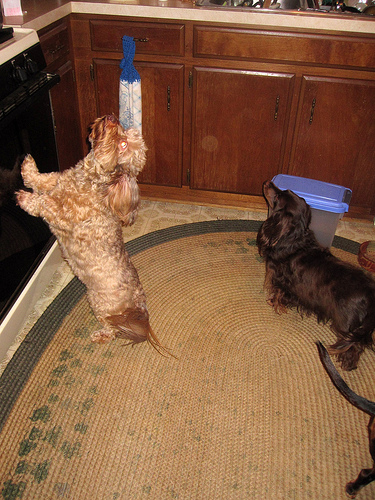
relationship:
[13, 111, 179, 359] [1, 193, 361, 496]
dog on floor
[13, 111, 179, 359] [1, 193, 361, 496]
dog near floor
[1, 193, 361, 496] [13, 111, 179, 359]
floor near dog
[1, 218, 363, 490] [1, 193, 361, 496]
rug on floor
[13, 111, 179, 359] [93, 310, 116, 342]
dog on legs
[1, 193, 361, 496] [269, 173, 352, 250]
floor on container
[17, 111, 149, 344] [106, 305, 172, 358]
dog has tail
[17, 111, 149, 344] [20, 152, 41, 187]
dog has paw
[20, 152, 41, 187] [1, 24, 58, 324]
paw on stove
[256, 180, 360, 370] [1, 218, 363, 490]
dog on rug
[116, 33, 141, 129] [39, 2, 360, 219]
towel hanging on cabinets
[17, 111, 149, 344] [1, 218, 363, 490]
dog standing on rug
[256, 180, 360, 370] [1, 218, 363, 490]
dog standing on rug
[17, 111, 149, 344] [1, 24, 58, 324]
dog jumping on stove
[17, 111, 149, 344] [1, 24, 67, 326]
dog jumping on stove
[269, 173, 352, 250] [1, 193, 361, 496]
container on floor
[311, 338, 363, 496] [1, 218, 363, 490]
dog standing on rug